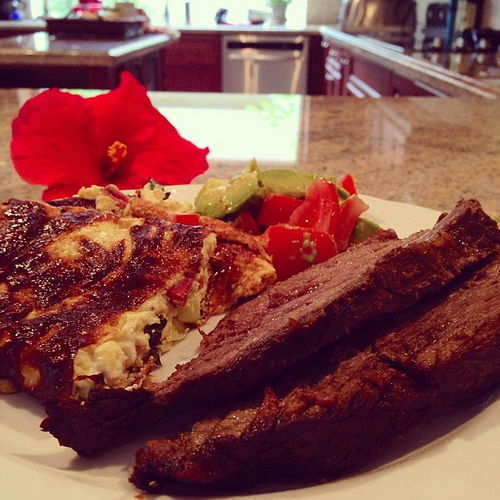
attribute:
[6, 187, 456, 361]
dish — white 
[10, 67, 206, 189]
flower — Red 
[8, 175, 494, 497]
meal — served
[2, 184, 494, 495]
plate — white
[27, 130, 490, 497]
table — granite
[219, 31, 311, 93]
dish washer — silver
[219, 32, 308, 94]
dishwasher — stainless steel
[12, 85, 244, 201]
flower — red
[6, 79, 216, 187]
flower — red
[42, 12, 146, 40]
basket — brown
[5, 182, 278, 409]
frittata — yellow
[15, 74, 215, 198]
flower — meal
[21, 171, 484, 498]
dish — ceramic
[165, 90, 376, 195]
counter — top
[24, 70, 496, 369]
counter — marble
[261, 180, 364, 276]
pepper — red 